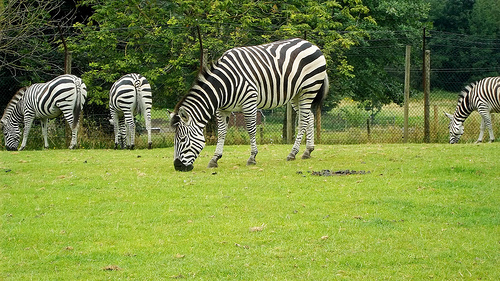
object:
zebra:
[0, 73, 88, 152]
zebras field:
[1, 36, 498, 191]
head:
[166, 109, 206, 171]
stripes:
[228, 39, 315, 93]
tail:
[133, 82, 144, 117]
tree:
[1, 2, 83, 82]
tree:
[78, 2, 212, 107]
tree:
[204, 2, 376, 79]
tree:
[351, 2, 432, 103]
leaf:
[468, 39, 479, 49]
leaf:
[364, 12, 381, 29]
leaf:
[277, 19, 298, 34]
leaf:
[162, 11, 179, 31]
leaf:
[70, 19, 87, 33]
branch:
[45, 1, 67, 18]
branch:
[48, 58, 68, 79]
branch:
[0, 43, 27, 63]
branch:
[4, 0, 25, 20]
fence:
[0, 22, 500, 149]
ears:
[167, 109, 174, 118]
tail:
[72, 78, 81, 129]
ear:
[178, 108, 191, 127]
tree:
[386, 0, 500, 102]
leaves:
[183, 0, 226, 13]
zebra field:
[1, 90, 500, 237]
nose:
[173, 158, 185, 171]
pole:
[421, 47, 430, 143]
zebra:
[442, 77, 500, 145]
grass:
[2, 146, 483, 279]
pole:
[402, 44, 412, 143]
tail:
[311, 72, 329, 113]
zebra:
[167, 37, 330, 173]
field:
[1, 141, 484, 267]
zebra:
[108, 72, 153, 149]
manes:
[173, 70, 204, 113]